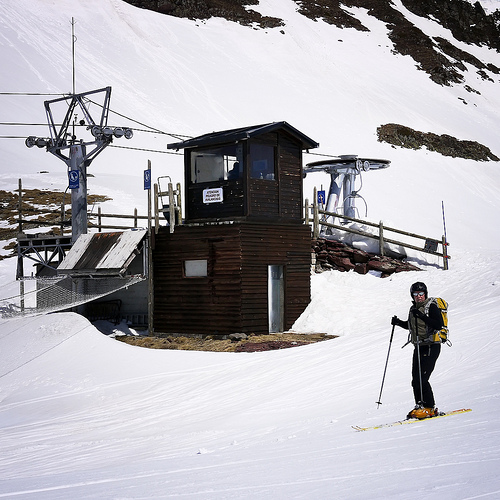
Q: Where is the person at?
A: Ski resort.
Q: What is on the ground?
A: Snow.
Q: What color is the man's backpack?
A: Yellow.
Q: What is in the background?
A: Mountain.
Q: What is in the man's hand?
A: Ski sticks.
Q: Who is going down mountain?
A: Skier.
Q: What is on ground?
A: Snow.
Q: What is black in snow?
A: Rock.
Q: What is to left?
A: Ski Lift.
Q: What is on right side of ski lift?
A: Lift off ramp.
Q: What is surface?
A: Smooth white snow.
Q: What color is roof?
A: Black.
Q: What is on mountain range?
A: Snow.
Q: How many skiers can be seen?
A: One.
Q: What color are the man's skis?
A: Yellow.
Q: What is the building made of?
A: Wood.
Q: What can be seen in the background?
A: Rocky patches.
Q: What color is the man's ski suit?
A: Black with some yellow.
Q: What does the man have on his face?
A: Goggles.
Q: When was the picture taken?
A: Daytime.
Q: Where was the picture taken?
A: Ski resort.